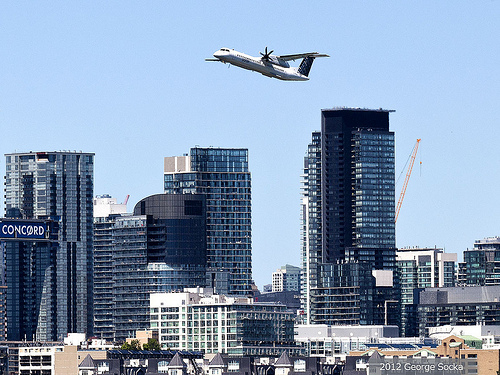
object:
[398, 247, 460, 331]
building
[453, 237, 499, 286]
building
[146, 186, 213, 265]
building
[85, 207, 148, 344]
building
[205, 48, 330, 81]
plane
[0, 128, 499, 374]
city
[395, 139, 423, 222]
crane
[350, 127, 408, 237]
building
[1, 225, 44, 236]
name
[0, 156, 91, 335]
building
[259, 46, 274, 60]
propeller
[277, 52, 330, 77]
stabilizer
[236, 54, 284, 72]
windows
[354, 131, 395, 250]
windows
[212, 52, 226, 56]
nose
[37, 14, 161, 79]
sky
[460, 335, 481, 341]
roof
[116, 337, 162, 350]
trees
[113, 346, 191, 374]
building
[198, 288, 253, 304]
chairs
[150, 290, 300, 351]
building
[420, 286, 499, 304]
roof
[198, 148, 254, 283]
buildings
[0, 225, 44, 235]
billboard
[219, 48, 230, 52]
cockpit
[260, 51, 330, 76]
wings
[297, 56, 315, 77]
tail